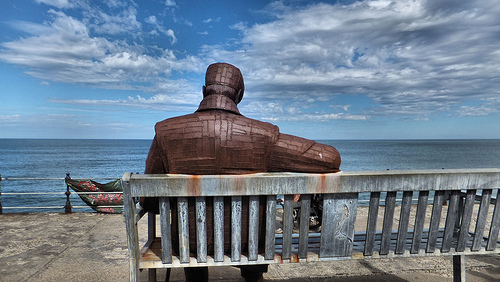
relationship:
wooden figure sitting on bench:
[148, 60, 335, 259] [122, 168, 500, 281]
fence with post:
[0, 174, 130, 209] [62, 170, 73, 214]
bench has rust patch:
[124, 175, 489, 277] [182, 177, 210, 194]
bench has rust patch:
[122, 168, 500, 281] [308, 176, 333, 192]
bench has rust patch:
[122, 168, 500, 281] [175, 173, 205, 194]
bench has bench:
[122, 168, 500, 281] [122, 168, 500, 281]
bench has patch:
[122, 168, 500, 281] [142, 239, 159, 258]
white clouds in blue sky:
[268, 34, 375, 89] [161, 17, 188, 48]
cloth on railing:
[51, 169, 123, 218] [14, 159, 110, 217]